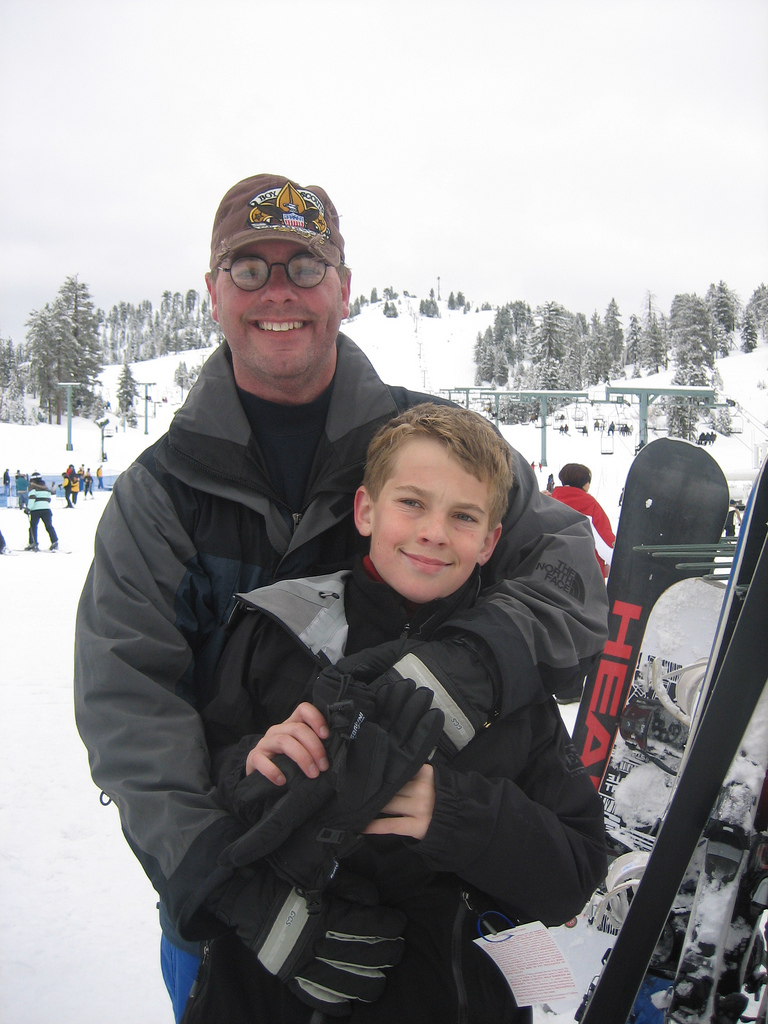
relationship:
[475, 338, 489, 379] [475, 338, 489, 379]
tree covered in snow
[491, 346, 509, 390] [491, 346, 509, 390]
tree covered in snow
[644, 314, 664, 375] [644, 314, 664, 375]
tree covered in snow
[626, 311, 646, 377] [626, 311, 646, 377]
tree covered in snow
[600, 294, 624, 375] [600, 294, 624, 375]
tree covered in snow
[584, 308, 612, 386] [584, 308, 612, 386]
tree covered in snow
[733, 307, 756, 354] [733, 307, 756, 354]
tree covered in snow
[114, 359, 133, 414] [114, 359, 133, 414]
tree covered in snow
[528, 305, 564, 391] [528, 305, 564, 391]
tree covered in snow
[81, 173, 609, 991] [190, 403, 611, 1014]
man standing with boy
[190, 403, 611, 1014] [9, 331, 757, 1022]
boy on ski slope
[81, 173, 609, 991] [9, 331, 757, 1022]
man on ski slope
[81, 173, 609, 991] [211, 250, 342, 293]
man wearing eyeglasses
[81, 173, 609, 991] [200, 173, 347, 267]
man wearing cap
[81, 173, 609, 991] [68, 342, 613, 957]
man wearing coat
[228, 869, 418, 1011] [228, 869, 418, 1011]
glove on hand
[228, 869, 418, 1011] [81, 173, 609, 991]
glove on man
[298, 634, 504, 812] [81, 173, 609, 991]
glove on man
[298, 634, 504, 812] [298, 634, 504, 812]
glove on hand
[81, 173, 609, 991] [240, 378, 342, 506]
man wearing shirt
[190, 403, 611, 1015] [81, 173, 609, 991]
boy standing with man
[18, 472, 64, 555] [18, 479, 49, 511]
person in coat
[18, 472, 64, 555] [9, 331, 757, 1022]
person on ski slope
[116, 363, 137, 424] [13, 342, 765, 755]
tree in a field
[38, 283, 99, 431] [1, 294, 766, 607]
tree in a field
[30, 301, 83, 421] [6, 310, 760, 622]
tree in a field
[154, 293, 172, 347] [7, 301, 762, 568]
tree in a field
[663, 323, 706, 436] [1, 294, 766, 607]
tree in a field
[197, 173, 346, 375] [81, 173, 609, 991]
head of a man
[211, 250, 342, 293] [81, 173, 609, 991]
eyeglasses on man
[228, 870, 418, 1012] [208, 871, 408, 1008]
glove on hand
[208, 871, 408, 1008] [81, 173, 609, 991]
hand on man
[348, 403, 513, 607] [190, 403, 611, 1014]
head of boy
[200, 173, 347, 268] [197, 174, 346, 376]
cap on head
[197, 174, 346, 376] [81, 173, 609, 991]
head of man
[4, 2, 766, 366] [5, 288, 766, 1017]
sky above land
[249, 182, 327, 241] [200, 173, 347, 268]
design on cap